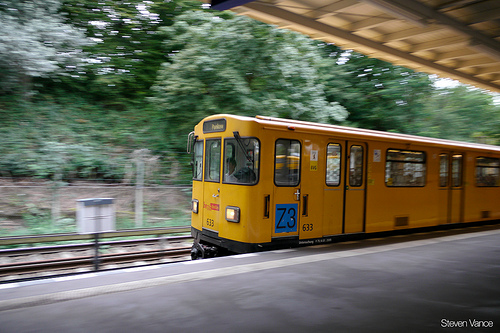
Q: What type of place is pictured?
A: It is a station.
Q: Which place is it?
A: It is a station.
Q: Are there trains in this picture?
A: Yes, there is a train.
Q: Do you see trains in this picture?
A: Yes, there is a train.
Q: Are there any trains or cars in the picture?
A: Yes, there is a train.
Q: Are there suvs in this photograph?
A: No, there are no suvs.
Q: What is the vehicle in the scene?
A: The vehicle is a train.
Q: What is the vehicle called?
A: The vehicle is a train.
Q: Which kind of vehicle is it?
A: The vehicle is a train.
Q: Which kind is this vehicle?
A: That is a train.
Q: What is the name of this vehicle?
A: That is a train.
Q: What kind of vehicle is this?
A: That is a train.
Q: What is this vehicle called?
A: That is a train.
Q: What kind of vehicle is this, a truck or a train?
A: That is a train.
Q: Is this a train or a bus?
A: This is a train.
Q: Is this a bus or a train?
A: This is a train.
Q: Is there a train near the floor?
A: Yes, there is a train near the floor.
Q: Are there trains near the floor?
A: Yes, there is a train near the floor.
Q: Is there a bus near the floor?
A: No, there is a train near the floor.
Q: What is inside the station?
A: The train is inside the station.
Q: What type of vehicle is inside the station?
A: The vehicle is a train.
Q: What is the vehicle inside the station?
A: The vehicle is a train.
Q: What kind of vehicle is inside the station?
A: The vehicle is a train.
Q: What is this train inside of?
A: The train is inside the station.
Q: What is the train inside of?
A: The train is inside the station.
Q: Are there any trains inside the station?
A: Yes, there is a train inside the station.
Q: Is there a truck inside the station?
A: No, there is a train inside the station.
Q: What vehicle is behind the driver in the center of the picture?
A: The vehicle is a train.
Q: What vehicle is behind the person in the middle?
A: The vehicle is a train.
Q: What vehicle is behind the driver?
A: The vehicle is a train.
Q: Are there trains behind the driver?
A: Yes, there is a train behind the driver.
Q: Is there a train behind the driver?
A: Yes, there is a train behind the driver.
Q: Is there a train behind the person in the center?
A: Yes, there is a train behind the driver.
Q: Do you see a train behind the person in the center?
A: Yes, there is a train behind the driver.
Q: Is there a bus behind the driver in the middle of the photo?
A: No, there is a train behind the driver.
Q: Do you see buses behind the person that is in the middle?
A: No, there is a train behind the driver.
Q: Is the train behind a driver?
A: Yes, the train is behind a driver.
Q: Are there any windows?
A: Yes, there is a window.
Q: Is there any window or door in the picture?
A: Yes, there is a window.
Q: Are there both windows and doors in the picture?
A: Yes, there are both a window and a door.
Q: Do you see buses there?
A: No, there are no buses.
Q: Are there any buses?
A: No, there are no buses.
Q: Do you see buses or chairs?
A: No, there are no buses or chairs.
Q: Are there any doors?
A: Yes, there are doors.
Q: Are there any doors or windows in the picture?
A: Yes, there are doors.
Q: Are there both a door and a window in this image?
A: Yes, there are both a door and a window.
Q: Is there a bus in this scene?
A: No, there are no buses.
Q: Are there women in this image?
A: No, there are no women.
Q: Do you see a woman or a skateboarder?
A: No, there are no women or skateboarders.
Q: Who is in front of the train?
A: The driver is in front of the train.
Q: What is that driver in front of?
A: The driver is in front of the train.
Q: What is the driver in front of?
A: The driver is in front of the train.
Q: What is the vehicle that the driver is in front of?
A: The vehicle is a train.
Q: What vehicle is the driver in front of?
A: The driver is in front of the train.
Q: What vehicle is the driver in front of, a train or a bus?
A: The driver is in front of a train.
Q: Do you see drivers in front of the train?
A: Yes, there is a driver in front of the train.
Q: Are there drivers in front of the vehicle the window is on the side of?
A: Yes, there is a driver in front of the train.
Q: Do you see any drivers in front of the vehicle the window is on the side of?
A: Yes, there is a driver in front of the train.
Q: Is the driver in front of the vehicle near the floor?
A: Yes, the driver is in front of the train.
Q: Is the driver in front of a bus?
A: No, the driver is in front of the train.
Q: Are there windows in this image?
A: Yes, there are windows.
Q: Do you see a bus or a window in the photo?
A: Yes, there are windows.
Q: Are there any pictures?
A: No, there are no pictures.